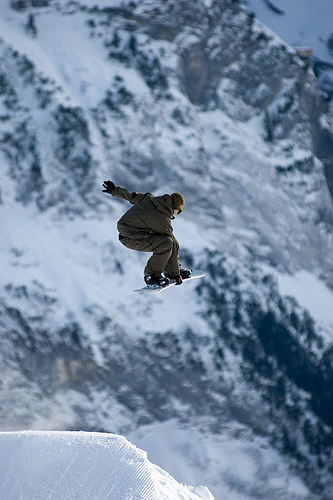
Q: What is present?
A: Snow.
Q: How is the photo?
A: Clear.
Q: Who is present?
A: A man.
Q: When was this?
A: Daytime.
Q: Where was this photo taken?
A: A ski slope.